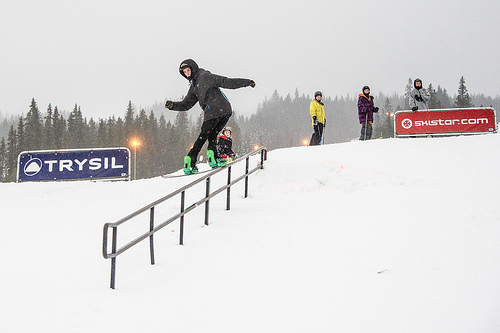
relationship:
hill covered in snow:
[0, 130, 499, 325] [181, 259, 484, 320]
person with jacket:
[306, 87, 329, 142] [309, 100, 327, 125]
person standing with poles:
[356, 85, 378, 141] [362, 108, 377, 138]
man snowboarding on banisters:
[164, 59, 255, 175] [102, 145, 268, 289]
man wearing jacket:
[301, 81, 326, 151] [310, 100, 330, 125]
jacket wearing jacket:
[357, 93, 376, 124] [356, 93, 371, 123]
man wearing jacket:
[171, 74, 247, 137] [410, 73, 437, 110]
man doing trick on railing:
[164, 59, 255, 175] [102, 145, 268, 288]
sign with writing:
[14, 145, 131, 182] [44, 155, 126, 172]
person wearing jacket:
[308, 91, 327, 147] [305, 98, 327, 126]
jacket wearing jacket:
[357, 93, 376, 124] [160, 69, 255, 130]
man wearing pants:
[164, 59, 255, 175] [190, 120, 222, 160]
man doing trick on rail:
[164, 59, 255, 175] [97, 153, 276, 287]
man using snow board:
[164, 59, 255, 175] [166, 155, 213, 175]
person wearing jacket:
[347, 86, 395, 172] [360, 95, 371, 119]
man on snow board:
[164, 59, 255, 175] [161, 166, 221, 179]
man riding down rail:
[164, 59, 255, 175] [102, 139, 269, 287]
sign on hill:
[14, 145, 131, 182] [0, 130, 499, 325]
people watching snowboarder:
[310, 78, 430, 145] [160, 57, 262, 178]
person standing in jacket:
[308, 91, 327, 147] [302, 96, 332, 123]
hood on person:
[160, 47, 255, 158] [159, 60, 265, 165]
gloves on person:
[231, 67, 278, 99] [166, 60, 253, 179]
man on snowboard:
[164, 59, 255, 175] [159, 145, 266, 180]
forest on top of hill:
[5, 50, 497, 160] [0, 130, 499, 325]